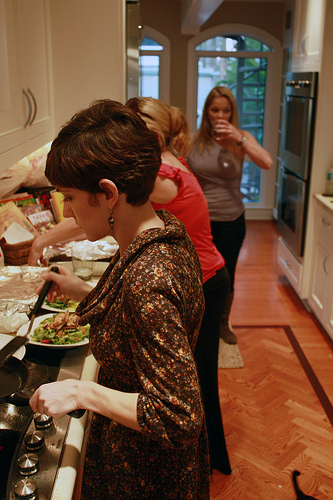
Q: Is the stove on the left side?
A: Yes, the stove is on the left of the image.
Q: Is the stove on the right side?
A: No, the stove is on the left of the image.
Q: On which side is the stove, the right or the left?
A: The stove is on the left of the image.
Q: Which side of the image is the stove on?
A: The stove is on the left of the image.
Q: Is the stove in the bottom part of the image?
A: Yes, the stove is in the bottom of the image.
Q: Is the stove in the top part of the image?
A: No, the stove is in the bottom of the image.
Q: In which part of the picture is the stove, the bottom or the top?
A: The stove is in the bottom of the image.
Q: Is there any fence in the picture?
A: No, there are no fences.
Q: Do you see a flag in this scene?
A: No, there are no flags.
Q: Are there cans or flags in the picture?
A: No, there are no flags or cans.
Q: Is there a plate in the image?
A: Yes, there is a plate.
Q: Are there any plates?
A: Yes, there is a plate.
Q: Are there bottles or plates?
A: Yes, there is a plate.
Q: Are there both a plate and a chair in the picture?
A: No, there is a plate but no chairs.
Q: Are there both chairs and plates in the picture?
A: No, there is a plate but no chairs.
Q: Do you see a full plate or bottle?
A: Yes, there is a full plate.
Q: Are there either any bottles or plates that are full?
A: Yes, the plate is full.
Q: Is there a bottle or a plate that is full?
A: Yes, the plate is full.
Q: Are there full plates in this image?
A: Yes, there is a full plate.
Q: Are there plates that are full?
A: Yes, there is a plate that is full.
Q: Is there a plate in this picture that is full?
A: Yes, there is a plate that is full.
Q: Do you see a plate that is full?
A: Yes, there is a plate that is full.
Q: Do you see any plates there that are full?
A: Yes, there is a plate that is full.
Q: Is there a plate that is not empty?
A: Yes, there is an full plate.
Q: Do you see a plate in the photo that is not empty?
A: Yes, there is an full plate.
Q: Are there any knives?
A: No, there are no knives.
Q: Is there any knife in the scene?
A: No, there are no knives.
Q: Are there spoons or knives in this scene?
A: No, there are no knives or spoons.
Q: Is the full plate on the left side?
A: Yes, the plate is on the left of the image.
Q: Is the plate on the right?
A: No, the plate is on the left of the image.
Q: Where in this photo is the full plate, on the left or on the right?
A: The plate is on the left of the image.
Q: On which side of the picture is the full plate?
A: The plate is on the left of the image.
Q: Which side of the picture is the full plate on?
A: The plate is on the left of the image.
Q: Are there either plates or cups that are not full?
A: No, there is a plate but it is full.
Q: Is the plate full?
A: Yes, the plate is full.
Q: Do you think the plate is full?
A: Yes, the plate is full.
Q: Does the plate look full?
A: Yes, the plate is full.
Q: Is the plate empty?
A: No, the plate is full.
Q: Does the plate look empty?
A: No, the plate is full.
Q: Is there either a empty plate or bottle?
A: No, there is a plate but it is full.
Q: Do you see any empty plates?
A: No, there is a plate but it is full.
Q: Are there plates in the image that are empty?
A: No, there is a plate but it is full.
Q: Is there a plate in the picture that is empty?
A: No, there is a plate but it is full.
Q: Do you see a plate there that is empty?
A: No, there is a plate but it is full.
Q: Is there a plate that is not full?
A: No, there is a plate but it is full.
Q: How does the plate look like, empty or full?
A: The plate is full.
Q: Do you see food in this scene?
A: Yes, there is food.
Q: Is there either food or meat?
A: Yes, there is food.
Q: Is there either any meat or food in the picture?
A: Yes, there is food.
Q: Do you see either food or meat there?
A: Yes, there is food.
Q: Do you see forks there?
A: No, there are no forks.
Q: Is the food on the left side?
A: Yes, the food is on the left of the image.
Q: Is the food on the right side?
A: No, the food is on the left of the image.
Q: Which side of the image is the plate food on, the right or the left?
A: The food is on the left of the image.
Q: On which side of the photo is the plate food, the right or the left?
A: The food is on the left of the image.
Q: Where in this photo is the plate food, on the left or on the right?
A: The food is on the left of the image.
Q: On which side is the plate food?
A: The food is on the left of the image.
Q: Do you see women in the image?
A: Yes, there is a woman.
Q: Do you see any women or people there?
A: Yes, there is a woman.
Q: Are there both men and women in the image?
A: No, there is a woman but no men.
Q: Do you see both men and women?
A: No, there is a woman but no men.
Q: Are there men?
A: No, there are no men.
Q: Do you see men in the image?
A: No, there are no men.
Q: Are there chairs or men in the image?
A: No, there are no men or chairs.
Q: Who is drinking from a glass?
A: The woman is drinking from a glass.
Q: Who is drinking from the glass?
A: The woman is drinking from a glass.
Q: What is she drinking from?
A: The woman is drinking from a glass.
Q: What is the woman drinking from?
A: The woman is drinking from a glass.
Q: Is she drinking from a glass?
A: Yes, the woman is drinking from a glass.